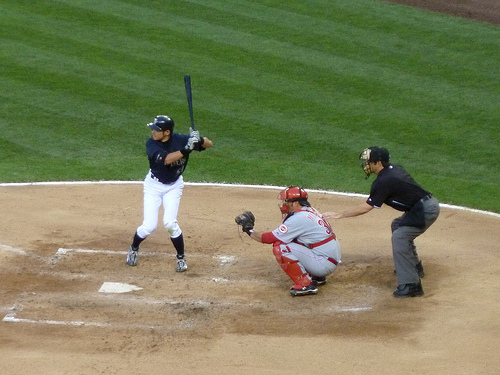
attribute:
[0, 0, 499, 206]
grass — green, short, dark, light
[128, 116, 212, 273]
player — batting, ready, standing, playing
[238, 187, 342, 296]
catcher — squatting, playing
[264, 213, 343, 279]
uniform — grey, red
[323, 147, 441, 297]
umpire — standing, playing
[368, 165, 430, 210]
shirt — black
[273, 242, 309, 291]
shin guards — red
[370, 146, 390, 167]
hat — black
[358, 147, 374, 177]
face mask — protective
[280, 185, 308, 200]
helmet — protective, red, black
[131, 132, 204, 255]
uniform — black, white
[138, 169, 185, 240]
pants — white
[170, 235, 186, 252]
sock — blue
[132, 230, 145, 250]
sock — blue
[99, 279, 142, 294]
home plate — triangle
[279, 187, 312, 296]
gear — red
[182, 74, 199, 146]
bat — black